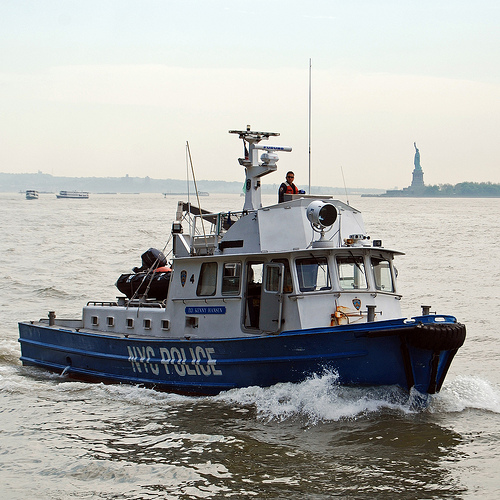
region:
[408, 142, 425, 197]
The statue of libertylooks smallon its'pedistel.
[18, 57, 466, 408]
The NYC patrol boat is blue and white.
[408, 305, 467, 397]
The bow has a tire bumper and tie off above it.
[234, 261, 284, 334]
The white cabin door is open.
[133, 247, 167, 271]
A black outboard motor is turned up.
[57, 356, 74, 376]
Water is coming out of the hole.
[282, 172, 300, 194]
The man is wearing an orange vest.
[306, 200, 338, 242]
A searchlight is mounted on the pole.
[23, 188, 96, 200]
Two boats are moving in different directions.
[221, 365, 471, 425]
The boat moving in the water causing a wave.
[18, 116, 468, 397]
A white and blue metal boat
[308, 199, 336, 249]
A search light mounted on a boat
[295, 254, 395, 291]
Windows on the front of a boat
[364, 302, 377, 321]
A mount for tying rope onto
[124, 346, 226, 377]
An NYC Police sign on a boat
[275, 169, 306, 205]
A police officer on a boat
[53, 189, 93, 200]
A ferry in the background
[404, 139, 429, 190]
The statue of liberty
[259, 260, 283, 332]
A boat cabin door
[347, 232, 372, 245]
A boat mounted bull horn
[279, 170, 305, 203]
pilot of the nyc police boat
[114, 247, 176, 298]
life raft of the nyc boat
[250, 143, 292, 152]
radar equipment for the blue and white boat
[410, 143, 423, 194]
statue of liberty in the distance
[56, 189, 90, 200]
ferry boat in the far north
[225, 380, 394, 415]
waves created by the boat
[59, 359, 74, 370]
water outlet for the police boat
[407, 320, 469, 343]
bumper for the nyc police boat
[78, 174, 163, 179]
city skyline in the distance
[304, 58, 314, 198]
communications antenna for the police boat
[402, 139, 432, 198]
statue of liberty in the distance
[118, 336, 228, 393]
nyc police on the side of the boat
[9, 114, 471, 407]
boat on the water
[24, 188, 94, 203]
boats in the distance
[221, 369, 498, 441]
waves splashing as the boat moves through the water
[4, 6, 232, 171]
clear sky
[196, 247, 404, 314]
windows on the boat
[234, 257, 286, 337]
door on the boat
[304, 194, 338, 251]
light on the front of the boat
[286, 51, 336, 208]
pole on the top of the boat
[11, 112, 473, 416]
A small white and blue boat voyaging across the water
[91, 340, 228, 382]
White lettering reading "NYC Police" written on the side of a blue background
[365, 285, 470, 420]
Blue colored prow of a boat gliding through the dark water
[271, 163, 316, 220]
Man standing on a boat wearing an orange and yellow life jacket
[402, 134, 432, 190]
Green statue of a woman holding a torch standing on a platform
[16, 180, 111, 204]
Two boats in the distance next to each other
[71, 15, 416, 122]
Pale blue sky with no clouds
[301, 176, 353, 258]
White painted search light that isn't on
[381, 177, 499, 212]
Piece of land protruding into the water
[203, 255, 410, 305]
Windows built into a white boat